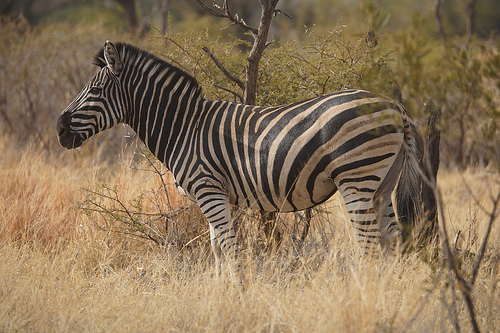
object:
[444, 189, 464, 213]
grass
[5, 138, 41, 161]
grass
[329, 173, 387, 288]
legs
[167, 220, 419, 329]
grass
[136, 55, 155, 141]
stripes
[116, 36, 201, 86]
mane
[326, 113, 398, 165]
lines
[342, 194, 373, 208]
stripes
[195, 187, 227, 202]
lines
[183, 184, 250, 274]
leg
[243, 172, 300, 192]
stipes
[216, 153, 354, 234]
belly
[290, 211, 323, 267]
tree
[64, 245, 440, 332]
grass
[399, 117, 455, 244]
zebra's tail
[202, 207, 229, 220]
stripes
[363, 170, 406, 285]
zebra's legs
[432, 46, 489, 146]
no object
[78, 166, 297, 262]
bushes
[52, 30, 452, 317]
zebra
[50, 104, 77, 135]
nose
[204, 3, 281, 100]
tree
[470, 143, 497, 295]
twigs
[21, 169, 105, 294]
grass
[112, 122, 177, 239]
branches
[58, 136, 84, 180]
grass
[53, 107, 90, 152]
mouth